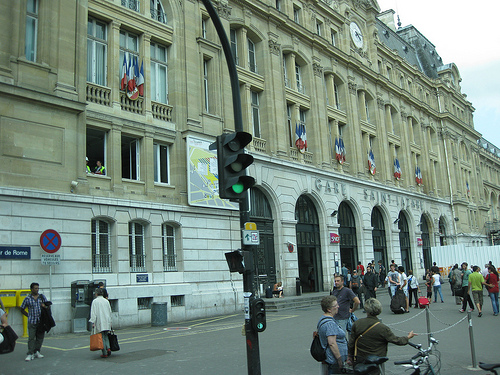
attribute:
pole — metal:
[201, 2, 260, 374]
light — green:
[209, 132, 254, 202]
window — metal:
[252, 90, 262, 140]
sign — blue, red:
[42, 230, 63, 254]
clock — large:
[347, 23, 365, 51]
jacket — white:
[89, 299, 113, 336]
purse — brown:
[109, 336, 119, 353]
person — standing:
[349, 299, 414, 375]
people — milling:
[20, 261, 499, 374]